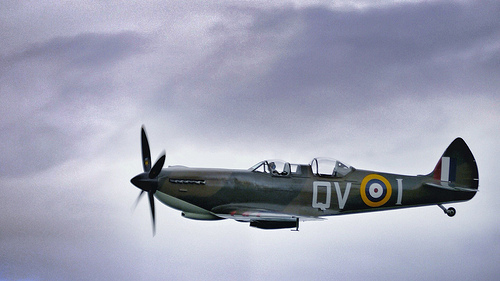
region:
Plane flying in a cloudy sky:
[91, 113, 487, 247]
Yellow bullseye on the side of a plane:
[357, 169, 394, 208]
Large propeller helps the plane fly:
[113, 120, 168, 245]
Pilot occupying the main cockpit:
[253, 157, 295, 182]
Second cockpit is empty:
[307, 154, 357, 181]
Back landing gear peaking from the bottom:
[431, 198, 463, 218]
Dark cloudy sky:
[1, 0, 498, 279]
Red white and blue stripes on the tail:
[432, 155, 457, 185]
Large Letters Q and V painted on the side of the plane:
[310, 177, 354, 213]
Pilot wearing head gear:
[264, 157, 284, 177]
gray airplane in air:
[119, 131, 439, 232]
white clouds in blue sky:
[17, 12, 109, 73]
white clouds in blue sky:
[14, 60, 75, 117]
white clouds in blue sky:
[77, 68, 116, 110]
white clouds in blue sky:
[22, 104, 112, 184]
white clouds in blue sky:
[9, 160, 112, 244]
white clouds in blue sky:
[160, 31, 228, 81]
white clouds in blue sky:
[277, 22, 377, 90]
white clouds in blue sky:
[373, 18, 466, 105]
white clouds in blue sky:
[193, 63, 299, 139]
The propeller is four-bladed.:
[131, 125, 169, 237]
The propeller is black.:
[131, 125, 168, 237]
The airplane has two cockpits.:
[248, 153, 351, 179]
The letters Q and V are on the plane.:
[311, 178, 353, 211]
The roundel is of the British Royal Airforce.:
[358, 170, 392, 207]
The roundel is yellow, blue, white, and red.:
[359, 173, 391, 208]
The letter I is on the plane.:
[395, 175, 410, 207]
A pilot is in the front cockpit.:
[266, 160, 279, 172]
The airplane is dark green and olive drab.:
[130, 123, 481, 233]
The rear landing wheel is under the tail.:
[430, 201, 457, 216]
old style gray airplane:
[99, 126, 480, 221]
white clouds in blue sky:
[18, 104, 80, 155]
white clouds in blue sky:
[29, 159, 124, 206]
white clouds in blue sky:
[23, 196, 107, 256]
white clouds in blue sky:
[216, 26, 358, 93]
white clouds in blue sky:
[306, 73, 408, 143]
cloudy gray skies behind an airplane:
[20, 13, 493, 271]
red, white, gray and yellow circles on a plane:
[357, 169, 394, 212]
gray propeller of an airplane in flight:
[125, 123, 182, 233]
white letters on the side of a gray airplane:
[309, 178, 354, 213]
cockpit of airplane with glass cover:
[250, 153, 291, 179]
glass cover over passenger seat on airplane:
[305, 153, 353, 178]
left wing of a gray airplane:
[207, 196, 331, 238]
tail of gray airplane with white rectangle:
[414, 133, 481, 234]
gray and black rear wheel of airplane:
[430, 198, 463, 223]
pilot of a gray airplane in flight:
[257, 153, 285, 178]